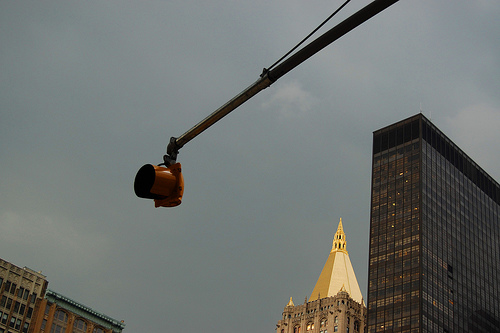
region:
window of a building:
[374, 153, 390, 166]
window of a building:
[374, 170, 387, 185]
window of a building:
[372, 182, 386, 198]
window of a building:
[372, 198, 389, 215]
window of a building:
[375, 213, 386, 232]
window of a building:
[371, 231, 388, 244]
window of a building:
[374, 247, 387, 256]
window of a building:
[375, 259, 389, 270]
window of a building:
[370, 273, 384, 293]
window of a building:
[376, 292, 391, 312]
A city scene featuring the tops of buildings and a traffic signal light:
[0, 8, 479, 329]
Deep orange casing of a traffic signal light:
[106, 131, 213, 224]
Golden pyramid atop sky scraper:
[276, 213, 358, 331]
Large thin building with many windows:
[352, 131, 490, 325]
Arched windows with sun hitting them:
[259, 313, 358, 330]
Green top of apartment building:
[28, 289, 138, 327]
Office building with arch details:
[0, 268, 44, 322]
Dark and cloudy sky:
[7, 26, 318, 288]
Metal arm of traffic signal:
[164, 10, 354, 167]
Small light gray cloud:
[245, 63, 323, 141]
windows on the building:
[352, 104, 498, 329]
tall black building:
[353, 108, 499, 329]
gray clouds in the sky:
[0, 0, 499, 332]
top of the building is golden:
[294, 203, 362, 305]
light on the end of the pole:
[109, 109, 219, 229]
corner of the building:
[410, 105, 434, 331]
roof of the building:
[49, 290, 141, 330]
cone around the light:
[123, 147, 198, 215]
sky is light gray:
[1, 0, 493, 331]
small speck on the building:
[386, 222, 398, 230]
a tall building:
[372, 115, 494, 324]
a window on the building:
[377, 205, 392, 222]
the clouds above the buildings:
[17, 29, 364, 252]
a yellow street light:
[133, 158, 186, 203]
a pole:
[157, 18, 371, 130]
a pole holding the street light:
[126, 14, 392, 227]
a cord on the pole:
[255, 20, 357, 64]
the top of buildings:
[6, 270, 93, 325]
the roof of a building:
[312, 216, 369, 298]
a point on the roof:
[318, 207, 359, 264]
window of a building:
[383, 151, 398, 165]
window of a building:
[385, 167, 402, 175]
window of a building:
[378, 181, 393, 196]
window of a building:
[370, 199, 382, 216]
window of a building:
[388, 198, 402, 213]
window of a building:
[374, 220, 391, 230]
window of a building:
[376, 222, 391, 241]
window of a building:
[372, 236, 391, 251]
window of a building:
[400, 245, 413, 257]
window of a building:
[373, 264, 395, 279]